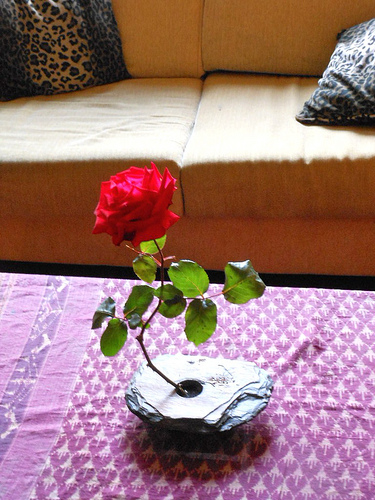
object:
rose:
[90, 161, 179, 248]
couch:
[0, 0, 374, 277]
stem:
[136, 236, 186, 394]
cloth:
[0, 272, 374, 498]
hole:
[176, 379, 203, 398]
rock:
[124, 356, 273, 433]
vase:
[123, 355, 271, 437]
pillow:
[0, 0, 131, 100]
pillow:
[295, 18, 375, 127]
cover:
[0, 271, 374, 499]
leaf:
[100, 318, 127, 356]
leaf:
[222, 258, 265, 306]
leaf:
[132, 252, 157, 286]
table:
[0, 272, 375, 500]